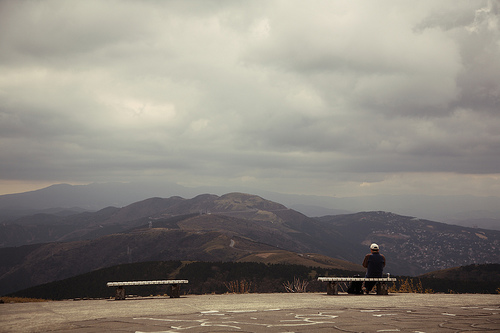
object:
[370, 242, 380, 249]
hat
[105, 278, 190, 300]
bench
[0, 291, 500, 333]
floor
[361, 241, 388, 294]
man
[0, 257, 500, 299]
hill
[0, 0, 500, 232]
sky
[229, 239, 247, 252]
road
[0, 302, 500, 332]
drawing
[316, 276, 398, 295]
bench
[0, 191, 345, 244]
hill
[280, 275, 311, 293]
branch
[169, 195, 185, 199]
summit